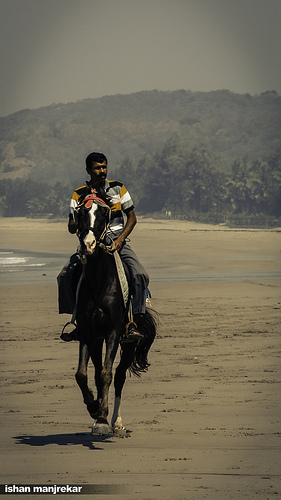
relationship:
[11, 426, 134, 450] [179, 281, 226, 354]
shadow on dirt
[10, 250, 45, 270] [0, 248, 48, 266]
water on sand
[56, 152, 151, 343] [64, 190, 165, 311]
man riding horse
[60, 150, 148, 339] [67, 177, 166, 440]
man riding on horse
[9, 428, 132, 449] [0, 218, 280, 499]
shadow on sand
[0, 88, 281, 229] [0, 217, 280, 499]
mountain behind beach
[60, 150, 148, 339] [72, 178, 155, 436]
man riding on horse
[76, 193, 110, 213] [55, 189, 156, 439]
headdress on horse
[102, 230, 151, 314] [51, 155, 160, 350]
pants on man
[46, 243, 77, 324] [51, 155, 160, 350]
pants on man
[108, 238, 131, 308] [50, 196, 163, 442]
blanket on horse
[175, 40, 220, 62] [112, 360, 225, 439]
ground contains tracks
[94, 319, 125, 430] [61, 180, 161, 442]
leg of horse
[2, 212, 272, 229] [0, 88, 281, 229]
edge bordering mountain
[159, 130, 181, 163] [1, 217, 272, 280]
tree growing alongside sand line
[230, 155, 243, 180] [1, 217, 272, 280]
tree growing alongside sand line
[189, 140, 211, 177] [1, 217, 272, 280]
tree growing alongside sand line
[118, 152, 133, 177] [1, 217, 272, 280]
tree growing alongside sand line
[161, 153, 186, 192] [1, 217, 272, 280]
tree growing alongside sand line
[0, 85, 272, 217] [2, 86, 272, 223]
mountain standing in background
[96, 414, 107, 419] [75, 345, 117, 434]
edge lining leg